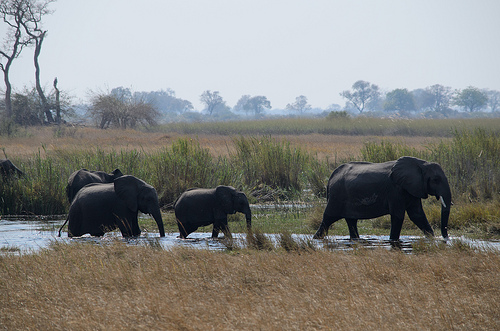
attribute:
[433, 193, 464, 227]
tusk — elephant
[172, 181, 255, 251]
elephant — young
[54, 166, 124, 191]
elephant — young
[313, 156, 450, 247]
elephant — older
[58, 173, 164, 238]
elephant — young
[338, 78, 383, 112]
tree — brown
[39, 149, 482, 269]
elephant — Wild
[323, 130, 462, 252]
elephant — really big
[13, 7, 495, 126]
sky — open, bright